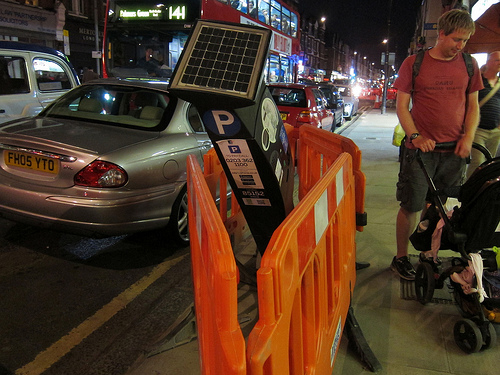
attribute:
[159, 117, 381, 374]
barricades — orange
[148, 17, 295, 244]
meter — broken, knocked over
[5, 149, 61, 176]
plate — yellow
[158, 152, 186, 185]
gas tank — covered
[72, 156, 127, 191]
taillight — red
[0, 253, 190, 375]
line — yellow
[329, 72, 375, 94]
lights — shining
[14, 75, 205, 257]
car — silver, parked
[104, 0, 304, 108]
bus — red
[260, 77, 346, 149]
car — red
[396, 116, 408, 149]
bag — yellow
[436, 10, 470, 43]
hair — blond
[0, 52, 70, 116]
car — white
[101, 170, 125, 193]
lights — white